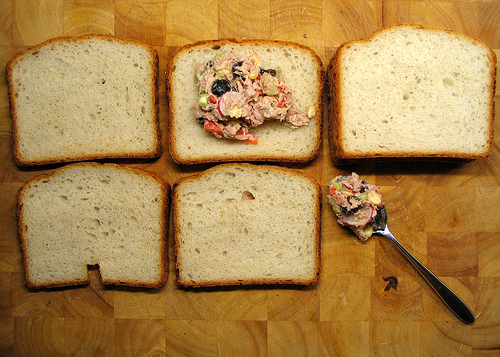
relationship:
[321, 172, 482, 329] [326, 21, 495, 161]
spoon near bread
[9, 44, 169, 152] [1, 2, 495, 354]
bread on a table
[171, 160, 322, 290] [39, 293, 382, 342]
bread on a table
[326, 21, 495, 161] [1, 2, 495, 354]
bread on table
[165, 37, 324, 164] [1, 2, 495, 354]
bread on table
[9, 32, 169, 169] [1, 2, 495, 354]
bread on table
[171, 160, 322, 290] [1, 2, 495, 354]
bread on table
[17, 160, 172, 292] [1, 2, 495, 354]
bread on table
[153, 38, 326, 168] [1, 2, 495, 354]
bread on table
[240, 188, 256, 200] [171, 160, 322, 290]
mark on bread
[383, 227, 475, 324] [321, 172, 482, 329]
handle on spoon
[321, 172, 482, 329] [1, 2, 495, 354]
spoon on table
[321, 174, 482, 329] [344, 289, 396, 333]
spoon on table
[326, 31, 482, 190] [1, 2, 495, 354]
bread on table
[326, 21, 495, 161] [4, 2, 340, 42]
bread on table